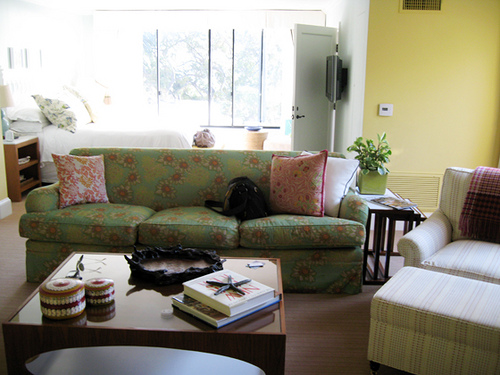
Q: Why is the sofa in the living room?
A: For people to sit.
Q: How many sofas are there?
A: One.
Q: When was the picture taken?
A: Daytime.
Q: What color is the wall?
A: Yellow.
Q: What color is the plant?
A: Green.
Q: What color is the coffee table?
A: Brown.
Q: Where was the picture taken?
A: The living room.